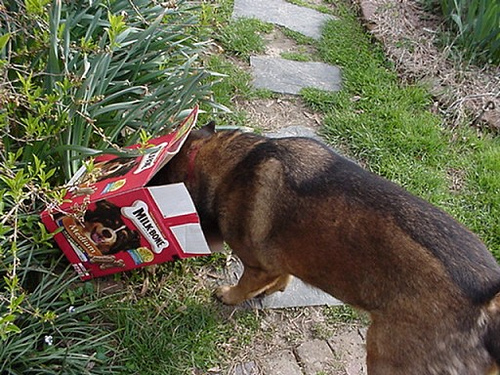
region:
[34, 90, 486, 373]
dog with it's head in a box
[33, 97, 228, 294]
red box on the ground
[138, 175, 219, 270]
flap on the top of the box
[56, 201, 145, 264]
picture of a dog on the box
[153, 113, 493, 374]
dog standing on the path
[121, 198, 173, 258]
drawing of a bone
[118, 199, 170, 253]
black writing on the bone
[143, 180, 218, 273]
flap is red and white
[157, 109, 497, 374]
brown and black dog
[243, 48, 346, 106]
stone tile on the ground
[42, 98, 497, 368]
a dog with his head in a milk bone box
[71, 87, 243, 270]
a dog's head in a cardboard box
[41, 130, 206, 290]
a red and white cardboard box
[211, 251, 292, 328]
the front legs of a dog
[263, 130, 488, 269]
the back of a dog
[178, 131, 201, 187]
the collar of a dog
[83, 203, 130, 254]
a picture of a dog's head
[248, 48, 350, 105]
a gray paving stone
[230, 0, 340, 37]
a gray paving stone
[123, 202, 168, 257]
the Milk Bone logo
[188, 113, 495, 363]
A large dog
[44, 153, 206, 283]
A red and white box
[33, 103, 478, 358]
A dog's head in a box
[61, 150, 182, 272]
A red box with Milk Bone written on it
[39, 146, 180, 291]
A red and white box with photo of a dog on it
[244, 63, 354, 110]
Cement stepping stones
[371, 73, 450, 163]
Green grass near stepping stones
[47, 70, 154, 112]
Tall green plants on left of stones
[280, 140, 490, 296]
A black streak down dogs back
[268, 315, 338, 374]
Brick stones under dog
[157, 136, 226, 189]
the dogs head is in the box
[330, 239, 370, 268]
the dog is brown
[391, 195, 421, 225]
the dog is black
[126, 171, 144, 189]
the box is red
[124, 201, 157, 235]
the bone is white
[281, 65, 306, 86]
the stepping stones are gray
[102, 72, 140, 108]
the stems are dark green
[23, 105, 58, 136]
the leaves are lime green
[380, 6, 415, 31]
the grass is dead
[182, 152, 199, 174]
the collar is red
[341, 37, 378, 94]
green grass between stone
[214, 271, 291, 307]
front leg of dog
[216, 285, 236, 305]
paws of dog leg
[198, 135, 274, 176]
furry neck of dog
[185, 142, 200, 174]
red belt across dog neck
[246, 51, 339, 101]
rocks used in making path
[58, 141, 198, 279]
dog head immersed in box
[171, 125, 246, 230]
dog with bend neck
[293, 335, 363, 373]
bricks lying on mud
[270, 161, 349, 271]
brown and black furry skin of dog